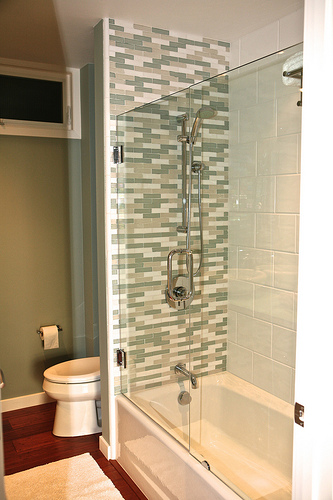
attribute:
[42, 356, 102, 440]
toilet — white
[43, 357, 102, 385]
seat — up, closed, down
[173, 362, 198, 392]
faucet — silver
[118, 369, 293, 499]
bathtub — white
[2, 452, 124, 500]
rug — white, cotton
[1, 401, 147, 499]
floor — brownish red, wood, wood grain, hardwood, brown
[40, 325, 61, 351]
toilet paper — hanging, rolled, white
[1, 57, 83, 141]
frame — white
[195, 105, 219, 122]
shower head — silver, removable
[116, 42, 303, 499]
shower door — glass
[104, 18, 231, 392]
tile — mosaic pattern, gray, neutral, white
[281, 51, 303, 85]
towel — white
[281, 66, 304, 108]
rack — silver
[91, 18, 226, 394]
wall — tile